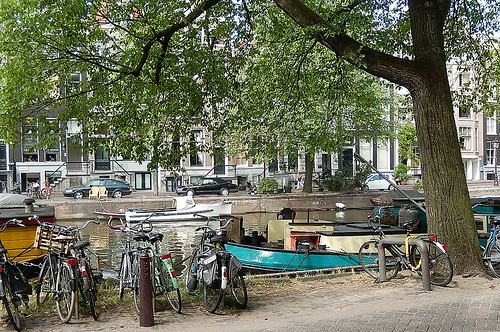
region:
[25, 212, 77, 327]
This is a bicycle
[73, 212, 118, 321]
This is a bicycle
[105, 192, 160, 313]
This is a bicycle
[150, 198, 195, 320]
This is a bicycle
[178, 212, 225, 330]
This is a bicycle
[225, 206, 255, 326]
This is a bicycle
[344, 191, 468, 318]
This is a bicycle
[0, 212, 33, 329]
This is a bicycle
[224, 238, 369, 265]
a blue boat in the water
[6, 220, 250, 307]
bikes in front of the water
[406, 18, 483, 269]
the trunk of a tree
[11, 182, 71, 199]
people standing on the sidewalk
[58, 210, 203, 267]
a body of water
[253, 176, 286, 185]
bushes next to the water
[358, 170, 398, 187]
a white car parked on the street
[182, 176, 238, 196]
a black car parked on the street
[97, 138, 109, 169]
the door to the building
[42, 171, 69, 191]
stairs going up to the building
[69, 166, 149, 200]
the van is parked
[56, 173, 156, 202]
van is dark blue in color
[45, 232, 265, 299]
bicycles are parked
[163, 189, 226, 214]
boat is white in color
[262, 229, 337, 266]
the boat is green blue in color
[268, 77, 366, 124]
the p[lant is green in color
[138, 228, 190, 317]
bicycle is green in color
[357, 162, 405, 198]
car is white in color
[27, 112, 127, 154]
the building is adjacent to the river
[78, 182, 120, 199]
the seats are light yellow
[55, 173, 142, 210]
This is a car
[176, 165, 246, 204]
This is a car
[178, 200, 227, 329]
This is a car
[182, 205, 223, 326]
This is a bicycle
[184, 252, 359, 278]
green boat on water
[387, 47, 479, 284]
brown trunk of tree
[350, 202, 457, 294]
bike parked near tree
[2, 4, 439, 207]
tree has sprawling branches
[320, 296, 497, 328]
sidewalk is light grey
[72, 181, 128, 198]
green car in distance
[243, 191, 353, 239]
brown wall behind boat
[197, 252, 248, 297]
bike has black tire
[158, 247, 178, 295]
green basket on bike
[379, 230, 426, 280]
grey pole near bike